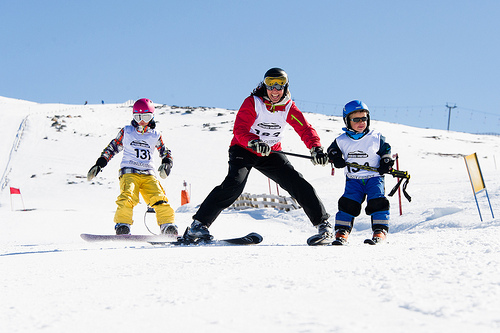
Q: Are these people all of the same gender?
A: No, they are both male and female.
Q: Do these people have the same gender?
A: No, they are both male and female.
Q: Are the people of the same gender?
A: No, they are both male and female.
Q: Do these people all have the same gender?
A: No, they are both male and female.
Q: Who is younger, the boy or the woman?
A: The boy is younger than the woman.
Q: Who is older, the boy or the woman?
A: The woman is older than the boy.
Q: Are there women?
A: Yes, there is a woman.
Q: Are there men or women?
A: Yes, there is a woman.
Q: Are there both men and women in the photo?
A: No, there is a woman but no men.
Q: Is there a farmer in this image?
A: No, there are no farmers.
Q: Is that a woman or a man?
A: That is a woman.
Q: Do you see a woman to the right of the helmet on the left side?
A: Yes, there is a woman to the right of the helmet.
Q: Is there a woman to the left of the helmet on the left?
A: No, the woman is to the right of the helmet.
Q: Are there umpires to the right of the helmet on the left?
A: No, there is a woman to the right of the helmet.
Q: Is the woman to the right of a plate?
A: No, the woman is to the right of the helmet.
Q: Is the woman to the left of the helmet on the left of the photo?
A: No, the woman is to the right of the helmet.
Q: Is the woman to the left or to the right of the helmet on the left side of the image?
A: The woman is to the right of the helmet.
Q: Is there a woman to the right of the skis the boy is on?
A: Yes, there is a woman to the right of the skis.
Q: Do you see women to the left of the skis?
A: No, the woman is to the right of the skis.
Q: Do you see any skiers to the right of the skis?
A: No, there is a woman to the right of the skis.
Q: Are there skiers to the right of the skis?
A: No, there is a woman to the right of the skis.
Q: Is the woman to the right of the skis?
A: Yes, the woman is to the right of the skis.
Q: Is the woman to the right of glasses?
A: No, the woman is to the right of the skis.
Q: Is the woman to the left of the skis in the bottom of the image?
A: No, the woman is to the right of the skis.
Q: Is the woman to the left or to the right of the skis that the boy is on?
A: The woman is to the right of the skis.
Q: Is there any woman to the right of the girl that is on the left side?
A: Yes, there is a woman to the right of the girl.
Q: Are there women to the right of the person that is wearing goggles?
A: Yes, there is a woman to the right of the girl.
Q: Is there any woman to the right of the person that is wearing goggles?
A: Yes, there is a woman to the right of the girl.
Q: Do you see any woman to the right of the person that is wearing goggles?
A: Yes, there is a woman to the right of the girl.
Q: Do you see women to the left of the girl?
A: No, the woman is to the right of the girl.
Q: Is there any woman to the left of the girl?
A: No, the woman is to the right of the girl.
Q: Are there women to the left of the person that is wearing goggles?
A: No, the woman is to the right of the girl.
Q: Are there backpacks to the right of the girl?
A: No, there is a woman to the right of the girl.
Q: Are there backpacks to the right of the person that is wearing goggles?
A: No, there is a woman to the right of the girl.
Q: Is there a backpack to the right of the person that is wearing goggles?
A: No, there is a woman to the right of the girl.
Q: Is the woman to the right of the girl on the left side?
A: Yes, the woman is to the right of the girl.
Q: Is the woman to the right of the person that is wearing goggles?
A: Yes, the woman is to the right of the girl.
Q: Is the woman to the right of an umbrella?
A: No, the woman is to the right of the girl.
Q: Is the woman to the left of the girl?
A: No, the woman is to the right of the girl.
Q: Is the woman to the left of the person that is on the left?
A: No, the woman is to the right of the girl.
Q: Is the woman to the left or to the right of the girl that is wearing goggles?
A: The woman is to the right of the girl.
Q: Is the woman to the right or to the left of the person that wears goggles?
A: The woman is to the right of the girl.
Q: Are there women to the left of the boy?
A: Yes, there is a woman to the left of the boy.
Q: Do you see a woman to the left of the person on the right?
A: Yes, there is a woman to the left of the boy.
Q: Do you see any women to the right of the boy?
A: No, the woman is to the left of the boy.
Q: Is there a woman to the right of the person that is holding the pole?
A: No, the woman is to the left of the boy.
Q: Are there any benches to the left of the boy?
A: No, there is a woman to the left of the boy.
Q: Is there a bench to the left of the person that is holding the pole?
A: No, there is a woman to the left of the boy.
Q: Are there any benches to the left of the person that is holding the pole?
A: No, there is a woman to the left of the boy.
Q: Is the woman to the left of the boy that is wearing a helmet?
A: Yes, the woman is to the left of the boy.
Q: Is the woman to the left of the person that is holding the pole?
A: Yes, the woman is to the left of the boy.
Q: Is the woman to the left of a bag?
A: No, the woman is to the left of the boy.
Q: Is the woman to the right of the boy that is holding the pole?
A: No, the woman is to the left of the boy.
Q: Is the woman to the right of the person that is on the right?
A: No, the woman is to the left of the boy.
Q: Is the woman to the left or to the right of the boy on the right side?
A: The woman is to the left of the boy.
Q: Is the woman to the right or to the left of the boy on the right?
A: The woman is to the left of the boy.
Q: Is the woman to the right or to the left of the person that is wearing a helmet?
A: The woman is to the left of the boy.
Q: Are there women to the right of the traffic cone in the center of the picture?
A: Yes, there is a woman to the right of the safety cone.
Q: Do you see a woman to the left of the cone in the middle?
A: No, the woman is to the right of the cone.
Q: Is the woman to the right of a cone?
A: Yes, the woman is to the right of a cone.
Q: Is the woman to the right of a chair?
A: No, the woman is to the right of a cone.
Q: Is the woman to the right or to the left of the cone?
A: The woman is to the right of the cone.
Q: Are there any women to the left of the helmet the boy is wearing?
A: Yes, there is a woman to the left of the helmet.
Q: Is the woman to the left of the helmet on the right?
A: Yes, the woman is to the left of the helmet.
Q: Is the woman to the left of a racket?
A: No, the woman is to the left of the helmet.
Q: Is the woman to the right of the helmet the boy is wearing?
A: No, the woman is to the left of the helmet.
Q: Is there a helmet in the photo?
A: Yes, there is a helmet.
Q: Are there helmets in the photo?
A: Yes, there is a helmet.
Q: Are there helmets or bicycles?
A: Yes, there is a helmet.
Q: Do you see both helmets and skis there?
A: Yes, there are both a helmet and skis.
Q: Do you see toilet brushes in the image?
A: No, there are no toilet brushes.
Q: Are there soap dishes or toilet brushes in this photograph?
A: No, there are no toilet brushes or soap dishes.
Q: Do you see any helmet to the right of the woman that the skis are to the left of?
A: Yes, there is a helmet to the right of the woman.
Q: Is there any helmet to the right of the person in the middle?
A: Yes, there is a helmet to the right of the woman.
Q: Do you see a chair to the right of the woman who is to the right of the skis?
A: No, there is a helmet to the right of the woman.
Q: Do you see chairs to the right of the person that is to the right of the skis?
A: No, there is a helmet to the right of the woman.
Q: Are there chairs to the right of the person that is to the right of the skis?
A: No, there is a helmet to the right of the woman.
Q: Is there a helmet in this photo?
A: Yes, there is a helmet.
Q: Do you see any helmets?
A: Yes, there is a helmet.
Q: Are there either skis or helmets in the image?
A: Yes, there is a helmet.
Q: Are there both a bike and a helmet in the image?
A: No, there is a helmet but no bikes.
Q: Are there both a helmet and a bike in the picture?
A: No, there is a helmet but no bikes.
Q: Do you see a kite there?
A: No, there are no kites.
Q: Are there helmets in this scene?
A: Yes, there is a helmet.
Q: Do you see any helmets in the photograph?
A: Yes, there is a helmet.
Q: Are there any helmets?
A: Yes, there is a helmet.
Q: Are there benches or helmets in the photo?
A: Yes, there is a helmet.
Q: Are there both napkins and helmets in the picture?
A: No, there is a helmet but no napkins.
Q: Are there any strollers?
A: No, there are no strollers.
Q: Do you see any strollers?
A: No, there are no strollers.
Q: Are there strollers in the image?
A: No, there are no strollers.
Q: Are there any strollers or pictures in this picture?
A: No, there are no strollers or pictures.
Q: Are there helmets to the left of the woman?
A: Yes, there is a helmet to the left of the woman.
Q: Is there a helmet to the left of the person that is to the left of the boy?
A: Yes, there is a helmet to the left of the woman.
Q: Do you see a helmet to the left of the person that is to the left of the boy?
A: Yes, there is a helmet to the left of the woman.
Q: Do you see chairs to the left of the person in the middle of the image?
A: No, there is a helmet to the left of the woman.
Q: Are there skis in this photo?
A: Yes, there are skis.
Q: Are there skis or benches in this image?
A: Yes, there are skis.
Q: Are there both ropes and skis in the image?
A: No, there are skis but no ropes.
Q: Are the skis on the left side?
A: Yes, the skis are on the left of the image.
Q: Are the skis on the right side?
A: No, the skis are on the left of the image.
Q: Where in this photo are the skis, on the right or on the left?
A: The skis are on the left of the image.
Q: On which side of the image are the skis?
A: The skis are on the left of the image.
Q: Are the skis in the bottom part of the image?
A: Yes, the skis are in the bottom of the image.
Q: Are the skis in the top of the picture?
A: No, the skis are in the bottom of the image.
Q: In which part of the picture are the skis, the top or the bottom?
A: The skis are in the bottom of the image.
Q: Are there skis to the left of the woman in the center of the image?
A: Yes, there are skis to the left of the woman.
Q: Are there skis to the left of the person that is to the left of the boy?
A: Yes, there are skis to the left of the woman.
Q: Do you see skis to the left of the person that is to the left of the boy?
A: Yes, there are skis to the left of the woman.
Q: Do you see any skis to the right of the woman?
A: No, the skis are to the left of the woman.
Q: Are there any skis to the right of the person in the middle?
A: No, the skis are to the left of the woman.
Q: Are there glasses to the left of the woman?
A: No, there are skis to the left of the woman.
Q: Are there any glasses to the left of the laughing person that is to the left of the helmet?
A: No, there are skis to the left of the woman.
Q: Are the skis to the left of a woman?
A: Yes, the skis are to the left of a woman.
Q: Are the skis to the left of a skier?
A: No, the skis are to the left of a woman.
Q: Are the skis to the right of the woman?
A: No, the skis are to the left of the woman.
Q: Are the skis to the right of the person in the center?
A: No, the skis are to the left of the woman.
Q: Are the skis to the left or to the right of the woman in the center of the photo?
A: The skis are to the left of the woman.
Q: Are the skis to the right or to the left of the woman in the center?
A: The skis are to the left of the woman.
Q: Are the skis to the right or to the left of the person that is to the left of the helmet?
A: The skis are to the left of the woman.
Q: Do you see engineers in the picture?
A: No, there are no engineers.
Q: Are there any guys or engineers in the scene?
A: No, there are no engineers or guys.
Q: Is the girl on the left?
A: Yes, the girl is on the left of the image.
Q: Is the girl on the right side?
A: No, the girl is on the left of the image.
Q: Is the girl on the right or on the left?
A: The girl is on the left of the image.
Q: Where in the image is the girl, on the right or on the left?
A: The girl is on the left of the image.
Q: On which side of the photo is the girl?
A: The girl is on the left of the image.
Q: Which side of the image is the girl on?
A: The girl is on the left of the image.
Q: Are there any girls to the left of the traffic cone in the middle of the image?
A: Yes, there is a girl to the left of the traffic cone.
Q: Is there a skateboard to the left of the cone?
A: No, there is a girl to the left of the cone.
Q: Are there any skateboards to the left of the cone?
A: No, there is a girl to the left of the cone.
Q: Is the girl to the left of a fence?
A: No, the girl is to the left of the traffic cone.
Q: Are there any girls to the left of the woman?
A: Yes, there is a girl to the left of the woman.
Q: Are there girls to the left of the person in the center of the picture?
A: Yes, there is a girl to the left of the woman.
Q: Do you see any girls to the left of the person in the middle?
A: Yes, there is a girl to the left of the woman.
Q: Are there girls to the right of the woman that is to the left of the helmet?
A: No, the girl is to the left of the woman.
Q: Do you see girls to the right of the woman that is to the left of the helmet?
A: No, the girl is to the left of the woman.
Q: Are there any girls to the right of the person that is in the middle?
A: No, the girl is to the left of the woman.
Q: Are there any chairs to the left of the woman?
A: No, there is a girl to the left of the woman.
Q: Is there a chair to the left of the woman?
A: No, there is a girl to the left of the woman.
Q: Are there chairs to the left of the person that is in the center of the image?
A: No, there is a girl to the left of the woman.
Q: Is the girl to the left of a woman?
A: Yes, the girl is to the left of a woman.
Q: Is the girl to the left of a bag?
A: No, the girl is to the left of a woman.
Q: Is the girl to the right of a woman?
A: No, the girl is to the left of a woman.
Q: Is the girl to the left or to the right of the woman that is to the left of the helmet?
A: The girl is to the left of the woman.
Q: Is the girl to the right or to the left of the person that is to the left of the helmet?
A: The girl is to the left of the woman.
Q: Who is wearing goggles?
A: The girl is wearing goggles.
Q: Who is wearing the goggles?
A: The girl is wearing goggles.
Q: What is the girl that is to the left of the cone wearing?
A: The girl is wearing goggles.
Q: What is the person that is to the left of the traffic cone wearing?
A: The girl is wearing goggles.